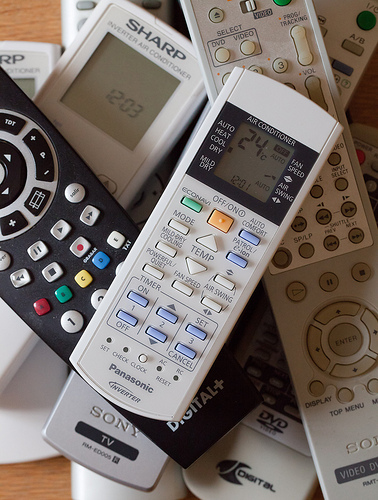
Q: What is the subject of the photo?
A: Remotes.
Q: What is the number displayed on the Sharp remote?
A: 12:03.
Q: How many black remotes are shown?
A: One.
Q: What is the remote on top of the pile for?
A: Air conditioner.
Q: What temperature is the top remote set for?
A: 24c.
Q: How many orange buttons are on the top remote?
A: One.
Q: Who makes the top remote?
A: Panasonic.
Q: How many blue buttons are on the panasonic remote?
A: Eight.